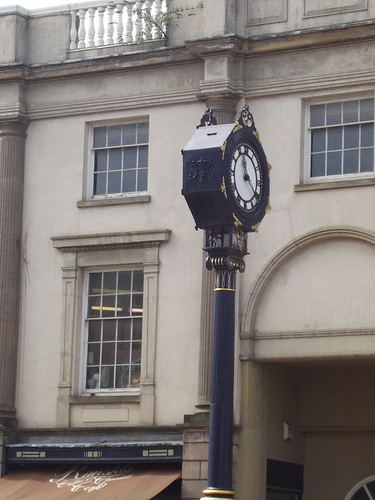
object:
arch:
[238, 234, 373, 339]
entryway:
[249, 360, 371, 496]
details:
[221, 176, 228, 199]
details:
[220, 141, 227, 160]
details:
[233, 120, 243, 133]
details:
[252, 130, 260, 143]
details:
[267, 162, 273, 178]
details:
[265, 201, 272, 213]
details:
[251, 222, 261, 233]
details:
[232, 212, 242, 227]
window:
[85, 270, 144, 389]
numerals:
[244, 201, 247, 209]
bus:
[218, 133, 270, 221]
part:
[36, 0, 41, 5]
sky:
[0, 0, 106, 10]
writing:
[49, 463, 133, 497]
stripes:
[202, 490, 234, 494]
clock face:
[228, 142, 264, 212]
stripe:
[211, 286, 236, 291]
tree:
[127, 6, 172, 38]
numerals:
[251, 200, 255, 208]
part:
[0, 23, 373, 119]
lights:
[132, 307, 143, 312]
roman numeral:
[244, 145, 249, 154]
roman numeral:
[251, 153, 254, 159]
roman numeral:
[255, 165, 259, 171]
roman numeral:
[257, 180, 261, 187]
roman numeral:
[254, 192, 260, 202]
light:
[91, 305, 122, 312]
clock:
[181, 121, 269, 232]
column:
[197, 249, 213, 441]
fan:
[93, 367, 112, 388]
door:
[265, 458, 303, 499]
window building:
[303, 96, 374, 184]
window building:
[86, 120, 148, 200]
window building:
[78, 267, 141, 397]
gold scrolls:
[205, 256, 245, 273]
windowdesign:
[50, 228, 171, 428]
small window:
[92, 122, 148, 194]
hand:
[242, 153, 248, 176]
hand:
[245, 175, 259, 200]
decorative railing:
[70, 0, 166, 51]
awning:
[0, 465, 182, 500]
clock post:
[201, 255, 241, 500]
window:
[308, 98, 373, 176]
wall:
[19, 242, 90, 338]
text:
[50, 465, 136, 493]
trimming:
[196, 484, 238, 498]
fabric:
[5, 475, 148, 498]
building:
[2, 0, 374, 498]